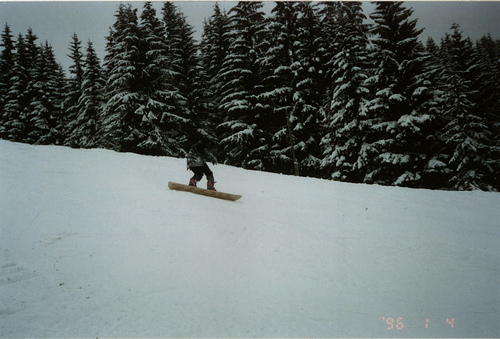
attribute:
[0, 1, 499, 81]
sky — cloudy, gray, overcast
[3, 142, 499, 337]
snow — pearl white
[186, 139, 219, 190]
person — snowboarding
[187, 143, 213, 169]
coat — heavy, gray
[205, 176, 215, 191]
snow boot — red, black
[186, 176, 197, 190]
snow boot — red, black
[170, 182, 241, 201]
snowboard — long, yellow, red, brown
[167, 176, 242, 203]
skyboard — yellow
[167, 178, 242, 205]
snowboard — long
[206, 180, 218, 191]
boot — yellow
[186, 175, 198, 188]
boot — yellow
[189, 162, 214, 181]
pants — black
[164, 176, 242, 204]
snowboard — light colored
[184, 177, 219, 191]
boots — red, black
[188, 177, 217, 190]
boots — black, red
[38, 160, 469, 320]
hillside — snowy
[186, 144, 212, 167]
coat — black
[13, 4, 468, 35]
sky — cloudy, grey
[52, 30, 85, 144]
tree — tall, evergreen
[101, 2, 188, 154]
tree — tall, evergreen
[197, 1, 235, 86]
tree — tall, evergreen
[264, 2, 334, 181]
tree — tall, evergreen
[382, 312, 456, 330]
date — red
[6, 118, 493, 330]
ski slope — well-groomed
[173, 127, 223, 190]
boarder — snow